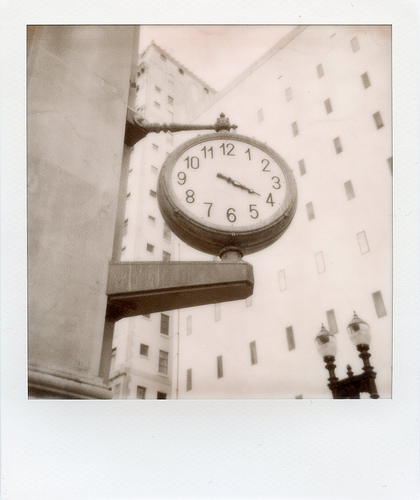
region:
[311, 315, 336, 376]
light on a post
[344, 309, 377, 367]
light on a post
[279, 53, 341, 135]
windows on the building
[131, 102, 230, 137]
extension of building to clock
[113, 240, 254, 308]
extension of building to clock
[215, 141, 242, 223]
numbers on the clock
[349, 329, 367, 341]
bulb inside the light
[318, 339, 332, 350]
bulb inside the light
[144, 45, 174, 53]
roof top of building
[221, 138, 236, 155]
black number on clock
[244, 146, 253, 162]
black number on clock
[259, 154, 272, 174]
black number on clock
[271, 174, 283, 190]
black number on clock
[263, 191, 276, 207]
black number on clock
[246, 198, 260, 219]
black number on clock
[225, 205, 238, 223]
black number on clock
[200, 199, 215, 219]
black number on clock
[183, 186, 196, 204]
black number on clock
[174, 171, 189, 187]
black number on clock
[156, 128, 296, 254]
Clock on a building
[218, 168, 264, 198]
Black hand on clock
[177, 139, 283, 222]
Numerical values on clock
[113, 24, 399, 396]
Buildings in the street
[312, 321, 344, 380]
Street light on stand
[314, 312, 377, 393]
Two unlit street lights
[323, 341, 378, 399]
A brown light stand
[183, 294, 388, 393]
Windows on a building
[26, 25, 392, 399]
A black and white photo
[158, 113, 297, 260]
Gray and white clock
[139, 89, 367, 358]
this is a clock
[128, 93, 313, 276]
the clock is round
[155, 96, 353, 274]
the clock says its four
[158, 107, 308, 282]
the face of the clock is white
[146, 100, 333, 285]
the numbers are black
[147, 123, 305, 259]
there are black numbers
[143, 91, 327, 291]
there are twelve numbers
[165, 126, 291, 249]
Clock is fixed to the wall.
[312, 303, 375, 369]
Two lamps are attached to the pole.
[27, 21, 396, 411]
Black and white picture.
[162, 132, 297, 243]
4.22 is the time shown.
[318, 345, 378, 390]
Pole is black color.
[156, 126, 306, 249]
Clock is round shape.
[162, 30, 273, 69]
Sky is white color.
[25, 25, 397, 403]
Day time picture.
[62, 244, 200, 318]
Rod is fixed to the wall.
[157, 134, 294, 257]
The round clock on the pole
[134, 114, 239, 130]
The pole holding the clock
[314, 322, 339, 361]
The white lamp on the streelight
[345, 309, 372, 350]
The lamp is clear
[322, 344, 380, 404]
The post holding the lamps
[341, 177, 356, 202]
The window on the building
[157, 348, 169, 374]
The window on the building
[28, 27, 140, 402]
The wall holding the clock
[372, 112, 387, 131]
The window on the building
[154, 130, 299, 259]
A round brown clock with white face.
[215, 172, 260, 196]
Black hands on a clock.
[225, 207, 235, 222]
Number 6 on a clock.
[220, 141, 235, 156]
Black number 12 on a clock.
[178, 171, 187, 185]
A black number 9.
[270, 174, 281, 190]
A black number 3.